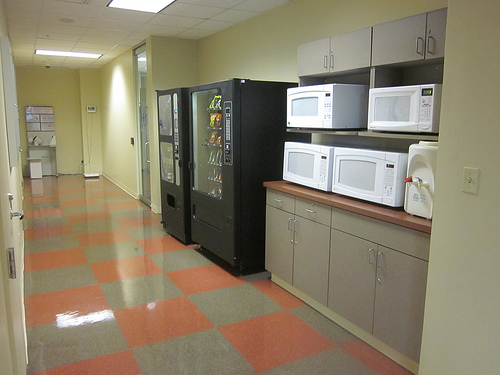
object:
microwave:
[287, 81, 368, 128]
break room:
[0, 0, 500, 375]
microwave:
[368, 83, 444, 134]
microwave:
[281, 140, 334, 193]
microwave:
[330, 145, 408, 209]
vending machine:
[156, 85, 187, 245]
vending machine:
[187, 78, 299, 278]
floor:
[23, 174, 418, 373]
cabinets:
[295, 27, 374, 77]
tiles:
[0, 0, 292, 71]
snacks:
[206, 92, 225, 197]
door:
[192, 85, 223, 202]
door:
[0, 17, 27, 359]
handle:
[10, 211, 25, 221]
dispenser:
[402, 140, 439, 221]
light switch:
[462, 165, 481, 196]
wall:
[419, 0, 500, 375]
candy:
[207, 150, 223, 199]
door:
[134, 44, 152, 211]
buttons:
[224, 115, 231, 142]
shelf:
[286, 127, 363, 137]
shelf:
[358, 129, 441, 142]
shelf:
[262, 178, 434, 235]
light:
[33, 49, 103, 59]